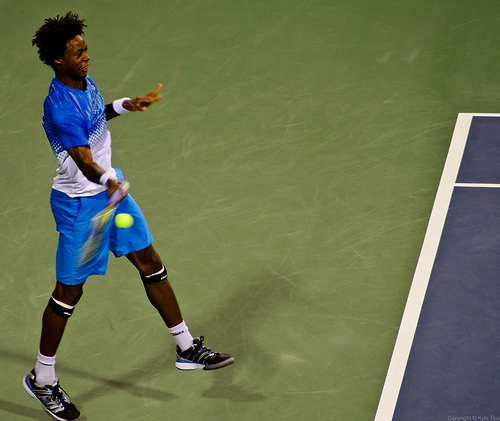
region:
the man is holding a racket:
[19, 25, 159, 270]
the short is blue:
[33, 158, 175, 279]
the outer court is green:
[235, 180, 314, 282]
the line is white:
[392, 255, 443, 303]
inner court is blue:
[444, 263, 494, 396]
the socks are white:
[18, 337, 264, 412]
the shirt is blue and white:
[14, 79, 187, 240]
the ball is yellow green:
[83, 191, 145, 248]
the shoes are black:
[8, 350, 255, 417]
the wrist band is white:
[95, 87, 155, 129]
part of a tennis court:
[354, 248, 462, 371]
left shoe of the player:
[175, 344, 242, 389]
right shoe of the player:
[15, 371, 77, 419]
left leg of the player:
[132, 265, 188, 316]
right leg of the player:
[36, 297, 59, 362]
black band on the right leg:
[34, 294, 76, 319]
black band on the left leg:
[142, 270, 176, 292]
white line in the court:
[392, 300, 419, 380]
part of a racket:
[78, 215, 103, 252]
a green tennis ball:
[111, 205, 151, 256]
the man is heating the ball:
[76, 196, 168, 281]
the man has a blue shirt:
[43, 196, 176, 278]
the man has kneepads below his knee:
[26, 286, 113, 328]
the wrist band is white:
[80, 165, 122, 200]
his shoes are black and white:
[156, 338, 256, 375]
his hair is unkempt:
[23, 17, 90, 72]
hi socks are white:
[37, 348, 69, 381]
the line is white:
[366, 226, 468, 373]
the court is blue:
[454, 267, 480, 382]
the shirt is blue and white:
[40, 98, 126, 187]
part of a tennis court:
[283, 144, 384, 248]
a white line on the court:
[381, 347, 400, 407]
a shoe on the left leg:
[183, 340, 233, 360]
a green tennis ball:
[115, 214, 145, 231]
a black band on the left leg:
[138, 257, 172, 289]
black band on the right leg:
[39, 297, 74, 322]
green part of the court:
[294, 260, 386, 335]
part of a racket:
[66, 209, 106, 248]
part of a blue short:
[48, 217, 75, 264]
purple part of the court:
[433, 244, 493, 383]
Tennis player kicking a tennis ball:
[12, 7, 254, 419]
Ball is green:
[102, 202, 137, 233]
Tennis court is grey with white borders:
[360, 84, 498, 405]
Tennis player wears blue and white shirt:
[18, 10, 246, 418]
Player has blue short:
[14, 4, 254, 419]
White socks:
[15, 315, 249, 415]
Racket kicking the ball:
[62, 170, 142, 277]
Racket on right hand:
[8, 5, 248, 419]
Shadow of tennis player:
[194, 227, 312, 341]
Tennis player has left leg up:
[11, 5, 249, 419]